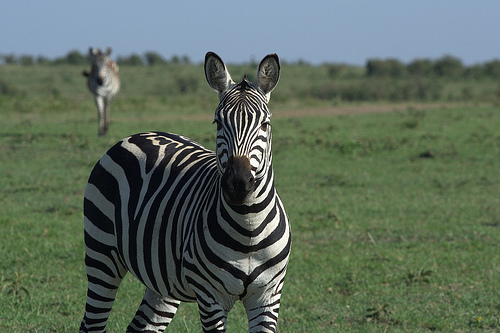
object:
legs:
[192, 291, 240, 333]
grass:
[0, 93, 500, 333]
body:
[94, 153, 272, 291]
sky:
[1, 1, 500, 63]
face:
[213, 84, 277, 199]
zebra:
[72, 48, 301, 333]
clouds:
[0, 0, 500, 63]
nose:
[219, 172, 256, 192]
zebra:
[80, 45, 123, 138]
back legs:
[77, 255, 125, 333]